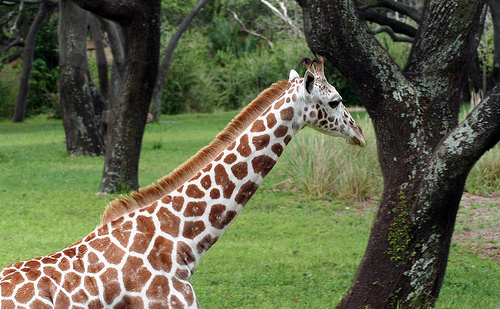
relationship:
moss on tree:
[299, 0, 499, 308] [294, 11, 498, 306]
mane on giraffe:
[88, 76, 289, 223] [4, 54, 371, 304]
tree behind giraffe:
[294, 0, 500, 308] [4, 54, 371, 304]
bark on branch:
[441, 116, 482, 162] [440, 83, 498, 178]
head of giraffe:
[285, 64, 367, 149] [4, 54, 371, 304]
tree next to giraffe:
[294, 11, 498, 306] [4, 54, 371, 304]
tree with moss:
[294, 11, 498, 306] [388, 187, 429, 301]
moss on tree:
[352, 59, 446, 288] [355, 112, 454, 305]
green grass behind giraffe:
[0, 102, 499, 309] [107, 107, 319, 277]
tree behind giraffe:
[294, 0, 500, 308] [66, 74, 342, 268]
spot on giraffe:
[276, 105, 295, 122] [214, 88, 302, 139]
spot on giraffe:
[276, 105, 295, 122] [96, 151, 363, 242]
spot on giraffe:
[257, 143, 280, 177] [16, 61, 326, 270]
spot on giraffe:
[276, 105, 295, 122] [67, 112, 409, 202]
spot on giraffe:
[180, 218, 207, 239] [53, 95, 363, 269]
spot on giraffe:
[167, 180, 206, 206] [77, 124, 328, 272]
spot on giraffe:
[180, 218, 207, 239] [45, 106, 334, 266]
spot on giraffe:
[180, 218, 207, 239] [45, 113, 309, 289]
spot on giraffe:
[144, 232, 178, 273] [4, 54, 371, 304]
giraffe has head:
[4, 54, 371, 304] [286, 45, 375, 154]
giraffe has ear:
[4, 54, 371, 304] [301, 64, 321, 96]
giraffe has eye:
[4, 54, 371, 304] [324, 89, 345, 110]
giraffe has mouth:
[4, 54, 371, 304] [348, 133, 371, 153]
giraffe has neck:
[4, 54, 371, 304] [173, 80, 300, 256]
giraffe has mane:
[4, 54, 371, 304] [88, 76, 289, 223]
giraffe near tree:
[4, 54, 371, 304] [294, 11, 498, 306]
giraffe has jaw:
[4, 54, 371, 304] [317, 111, 351, 138]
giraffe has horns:
[4, 54, 371, 304] [293, 53, 325, 76]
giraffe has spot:
[4, 54, 371, 304] [230, 158, 251, 179]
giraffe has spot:
[4, 54, 371, 304] [148, 233, 175, 273]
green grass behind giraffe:
[12, 74, 397, 296] [4, 54, 371, 304]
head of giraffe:
[285, 53, 365, 149] [4, 54, 371, 304]